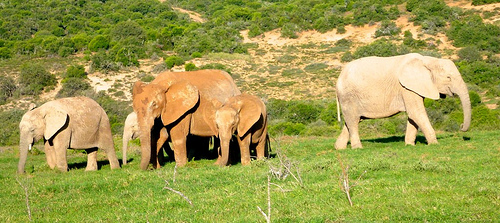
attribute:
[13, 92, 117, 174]
elephant — grouped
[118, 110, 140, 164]
elephant — grouped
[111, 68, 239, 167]
elephant — grouped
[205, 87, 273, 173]
elephant — grouped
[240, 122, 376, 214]
branches — small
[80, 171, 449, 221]
ground — out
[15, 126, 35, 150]
tusk — small, white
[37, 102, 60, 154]
ear — large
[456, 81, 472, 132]
trunk — large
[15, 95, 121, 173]
elephant — gray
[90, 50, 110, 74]
bush — green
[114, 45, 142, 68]
bush — green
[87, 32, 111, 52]
bush — green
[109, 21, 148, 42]
bush — green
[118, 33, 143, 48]
bush — green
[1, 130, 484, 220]
grass — green